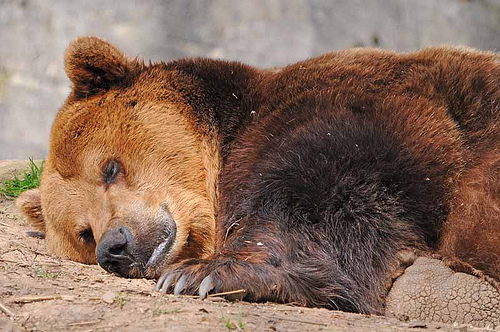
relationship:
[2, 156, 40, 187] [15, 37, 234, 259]
grass by head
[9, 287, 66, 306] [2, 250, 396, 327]
twig on bare ground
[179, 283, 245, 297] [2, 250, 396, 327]
twig on bare ground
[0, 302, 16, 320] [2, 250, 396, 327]
twig on bare ground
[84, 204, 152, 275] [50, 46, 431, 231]
nose of bear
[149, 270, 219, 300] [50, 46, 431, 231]
claws on bear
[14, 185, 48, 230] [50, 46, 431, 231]
ear on bear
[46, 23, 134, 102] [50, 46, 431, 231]
ear on bear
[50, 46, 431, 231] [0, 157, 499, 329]
bear almost touching ground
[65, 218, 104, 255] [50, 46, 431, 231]
eye of bear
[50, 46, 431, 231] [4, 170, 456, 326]
bear close to ground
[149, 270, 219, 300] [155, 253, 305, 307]
claws on hand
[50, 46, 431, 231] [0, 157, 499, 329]
bear laying on ground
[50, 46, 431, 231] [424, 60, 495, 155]
bear with brown spot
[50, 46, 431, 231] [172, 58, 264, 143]
bear with brown spot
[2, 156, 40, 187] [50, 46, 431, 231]
grass behind bear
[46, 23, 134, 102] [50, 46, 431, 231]
ear of a bear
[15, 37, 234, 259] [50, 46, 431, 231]
head of a bear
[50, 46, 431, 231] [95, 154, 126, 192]
bear with eye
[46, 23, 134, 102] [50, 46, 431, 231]
ear of bear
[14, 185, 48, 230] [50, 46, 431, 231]
ear of bear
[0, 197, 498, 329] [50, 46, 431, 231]
dirt under bear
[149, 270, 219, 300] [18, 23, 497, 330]
claws of bear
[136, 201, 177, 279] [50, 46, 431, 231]
mouth of bear